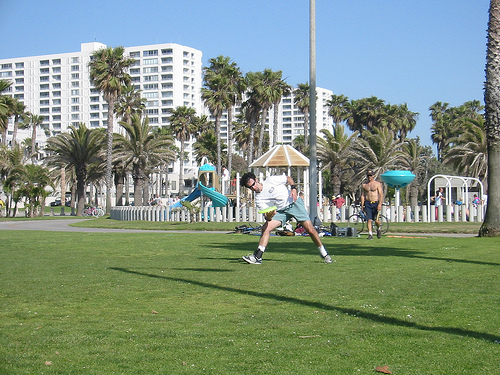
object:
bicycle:
[81, 203, 104, 218]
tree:
[4, 163, 54, 218]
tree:
[169, 104, 199, 199]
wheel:
[348, 214, 365, 234]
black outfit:
[427, 181, 483, 223]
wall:
[147, 102, 192, 137]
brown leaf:
[374, 366, 392, 374]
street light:
[291, 0, 335, 221]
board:
[159, 163, 228, 220]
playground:
[110, 144, 488, 222]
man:
[360, 170, 383, 240]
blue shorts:
[365, 200, 381, 221]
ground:
[337, 291, 435, 334]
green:
[0, 232, 497, 372]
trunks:
[76, 181, 86, 216]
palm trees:
[41, 122, 107, 216]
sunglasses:
[248, 181, 254, 188]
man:
[240, 172, 333, 265]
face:
[246, 179, 261, 193]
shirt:
[254, 175, 293, 211]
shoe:
[242, 253, 263, 265]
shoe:
[320, 254, 332, 263]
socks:
[317, 245, 327, 258]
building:
[0, 42, 202, 195]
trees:
[0, 79, 19, 148]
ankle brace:
[254, 248, 264, 258]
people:
[431, 190, 447, 220]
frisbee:
[258, 206, 278, 214]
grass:
[0, 235, 499, 375]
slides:
[183, 164, 230, 204]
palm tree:
[86, 45, 136, 215]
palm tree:
[201, 55, 244, 177]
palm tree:
[304, 123, 361, 196]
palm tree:
[428, 101, 450, 163]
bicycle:
[348, 200, 390, 234]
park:
[0, 190, 500, 373]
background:
[0, 0, 499, 243]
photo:
[1, 0, 500, 375]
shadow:
[108, 266, 500, 344]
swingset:
[427, 174, 483, 222]